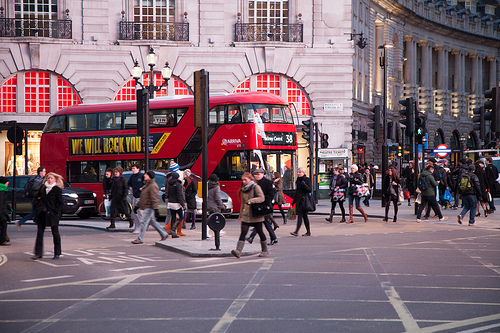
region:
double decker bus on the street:
[38, 90, 300, 220]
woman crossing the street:
[30, 170, 65, 260]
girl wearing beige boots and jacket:
[232, 172, 272, 257]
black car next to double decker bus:
[3, 174, 98, 222]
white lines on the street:
[0, 232, 498, 332]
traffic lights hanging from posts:
[469, 88, 499, 139]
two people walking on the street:
[322, 161, 372, 223]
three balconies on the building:
[0, 0, 310, 49]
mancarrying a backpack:
[454, 164, 484, 227]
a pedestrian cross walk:
[1, 226, 498, 331]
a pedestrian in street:
[233, 173, 269, 258]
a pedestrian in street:
[203, 175, 230, 237]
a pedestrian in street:
[252, 168, 278, 245]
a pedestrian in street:
[291, 168, 316, 239]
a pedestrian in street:
[324, 165, 344, 222]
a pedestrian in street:
[344, 163, 367, 223]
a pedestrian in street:
[380, 163, 401, 222]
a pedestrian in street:
[130, 168, 169, 245]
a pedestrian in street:
[28, 171, 65, 261]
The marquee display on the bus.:
[262, 132, 295, 148]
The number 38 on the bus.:
[284, 134, 292, 144]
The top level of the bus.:
[42, 93, 293, 147]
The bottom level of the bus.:
[49, 149, 300, 201]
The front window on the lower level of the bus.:
[248, 151, 295, 188]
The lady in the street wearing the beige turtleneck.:
[31, 170, 65, 260]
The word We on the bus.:
[68, 140, 86, 155]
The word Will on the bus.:
[78, 132, 102, 154]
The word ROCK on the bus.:
[99, 134, 124, 154]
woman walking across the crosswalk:
[230, 168, 271, 258]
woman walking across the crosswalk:
[29, 170, 69, 262]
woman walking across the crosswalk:
[345, 163, 372, 226]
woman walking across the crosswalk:
[379, 164, 405, 226]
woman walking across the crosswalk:
[325, 165, 350, 223]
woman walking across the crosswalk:
[289, 165, 320, 239]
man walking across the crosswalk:
[128, 168, 172, 246]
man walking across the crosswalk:
[412, 162, 446, 227]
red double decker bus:
[37, 89, 307, 221]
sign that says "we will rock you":
[66, 132, 168, 157]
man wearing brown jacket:
[143, 188, 153, 197]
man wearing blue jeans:
[138, 216, 149, 226]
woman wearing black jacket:
[51, 192, 62, 201]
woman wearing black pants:
[55, 222, 60, 244]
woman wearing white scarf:
[45, 183, 52, 190]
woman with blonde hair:
[57, 173, 64, 185]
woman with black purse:
[251, 201, 269, 213]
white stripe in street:
[392, 293, 413, 331]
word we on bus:
[65, 135, 85, 157]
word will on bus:
[78, 137, 105, 154]